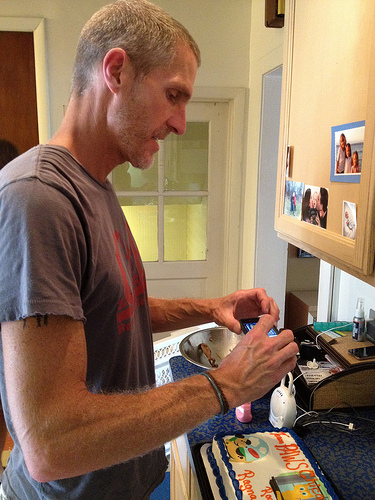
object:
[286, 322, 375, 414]
box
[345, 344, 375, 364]
things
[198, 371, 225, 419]
wrist band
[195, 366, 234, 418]
wrist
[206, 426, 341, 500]
icing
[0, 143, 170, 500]
shirt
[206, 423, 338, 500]
cake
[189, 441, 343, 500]
tray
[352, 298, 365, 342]
bottle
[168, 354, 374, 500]
counter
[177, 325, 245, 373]
bowl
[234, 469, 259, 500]
writing